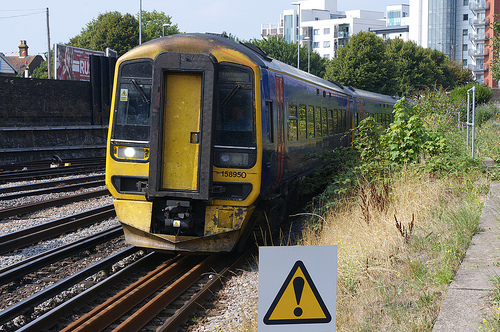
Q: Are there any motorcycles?
A: No, there are no motorcycles.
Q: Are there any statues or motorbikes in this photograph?
A: No, there are no motorbikes or statues.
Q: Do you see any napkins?
A: No, there are no napkins.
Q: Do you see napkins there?
A: No, there are no napkins.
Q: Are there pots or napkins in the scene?
A: No, there are no napkins or pots.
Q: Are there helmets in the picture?
A: No, there are no helmets.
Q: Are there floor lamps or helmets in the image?
A: No, there are no helmets or floor lamps.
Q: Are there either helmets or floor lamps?
A: No, there are no helmets or floor lamps.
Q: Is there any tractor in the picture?
A: No, there are no tractors.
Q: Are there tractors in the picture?
A: No, there are no tractors.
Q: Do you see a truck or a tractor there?
A: No, there are no tractors or trucks.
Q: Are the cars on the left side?
A: No, the cars are on the right of the image.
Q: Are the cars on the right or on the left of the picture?
A: The cars are on the right of the image.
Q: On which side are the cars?
A: The cars are on the right of the image.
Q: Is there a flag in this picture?
A: No, there are no flags.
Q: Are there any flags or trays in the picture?
A: No, there are no flags or trays.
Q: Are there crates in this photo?
A: No, there are no crates.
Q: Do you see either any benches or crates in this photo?
A: No, there are no crates or benches.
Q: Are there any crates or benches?
A: No, there are no crates or benches.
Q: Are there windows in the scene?
A: Yes, there is a window.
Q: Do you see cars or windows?
A: Yes, there is a window.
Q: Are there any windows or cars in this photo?
A: Yes, there is a window.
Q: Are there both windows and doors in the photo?
A: Yes, there are both a window and a door.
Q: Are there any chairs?
A: No, there are no chairs.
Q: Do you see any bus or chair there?
A: No, there are no chairs or buses.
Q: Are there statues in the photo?
A: No, there are no statues.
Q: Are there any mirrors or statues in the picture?
A: No, there are no statues or mirrors.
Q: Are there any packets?
A: No, there are no packets.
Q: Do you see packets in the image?
A: No, there are no packets.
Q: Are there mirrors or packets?
A: No, there are no packets or mirrors.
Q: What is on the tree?
A: The leaves are on the tree.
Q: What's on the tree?
A: The leaves are on the tree.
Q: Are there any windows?
A: Yes, there is a window.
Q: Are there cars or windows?
A: Yes, there is a window.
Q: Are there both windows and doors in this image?
A: Yes, there are both a window and a door.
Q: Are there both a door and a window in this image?
A: Yes, there are both a window and a door.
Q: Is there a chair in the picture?
A: No, there are no chairs.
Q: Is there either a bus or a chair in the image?
A: No, there are no chairs or buses.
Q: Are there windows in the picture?
A: Yes, there is a window.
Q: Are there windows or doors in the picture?
A: Yes, there is a window.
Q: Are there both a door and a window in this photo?
A: Yes, there are both a window and a door.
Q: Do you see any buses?
A: No, there are no buses.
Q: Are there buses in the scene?
A: No, there are no buses.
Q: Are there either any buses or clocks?
A: No, there are no buses or clocks.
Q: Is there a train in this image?
A: Yes, there is a train.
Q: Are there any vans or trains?
A: Yes, there is a train.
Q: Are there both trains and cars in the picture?
A: Yes, there are both a train and a car.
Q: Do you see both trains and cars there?
A: Yes, there are both a train and a car.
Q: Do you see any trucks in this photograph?
A: No, there are no trucks.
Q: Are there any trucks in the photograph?
A: No, there are no trucks.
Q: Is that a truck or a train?
A: That is a train.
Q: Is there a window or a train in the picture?
A: Yes, there is a window.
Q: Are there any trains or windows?
A: Yes, there is a window.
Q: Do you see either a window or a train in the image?
A: Yes, there is a window.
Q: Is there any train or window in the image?
A: Yes, there is a window.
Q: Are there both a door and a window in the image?
A: Yes, there are both a window and a door.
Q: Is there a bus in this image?
A: No, there are no buses.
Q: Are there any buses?
A: No, there are no buses.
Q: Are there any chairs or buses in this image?
A: No, there are no buses or chairs.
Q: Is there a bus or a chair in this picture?
A: No, there are no buses or chairs.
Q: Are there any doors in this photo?
A: Yes, there is a door.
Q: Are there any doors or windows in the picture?
A: Yes, there is a door.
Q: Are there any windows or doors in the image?
A: Yes, there is a door.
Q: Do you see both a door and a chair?
A: No, there is a door but no chairs.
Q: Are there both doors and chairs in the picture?
A: No, there is a door but no chairs.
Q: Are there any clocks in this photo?
A: No, there are no clocks.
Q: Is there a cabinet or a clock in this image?
A: No, there are no clocks or cabinets.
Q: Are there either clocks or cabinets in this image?
A: No, there are no clocks or cabinets.